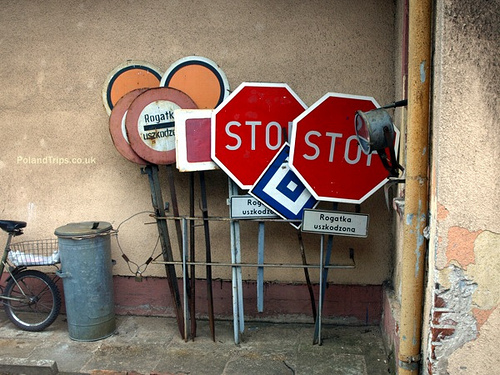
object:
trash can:
[52, 215, 122, 345]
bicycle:
[0, 214, 67, 335]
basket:
[7, 237, 66, 270]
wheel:
[3, 268, 63, 333]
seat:
[0, 217, 31, 240]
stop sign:
[284, 89, 404, 208]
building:
[2, 2, 499, 374]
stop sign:
[207, 80, 312, 315]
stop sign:
[285, 87, 402, 352]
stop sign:
[209, 76, 316, 193]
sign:
[123, 86, 201, 173]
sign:
[108, 87, 173, 168]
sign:
[178, 110, 214, 175]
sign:
[172, 107, 222, 172]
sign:
[159, 54, 233, 120]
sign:
[98, 58, 163, 127]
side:
[0, 1, 396, 327]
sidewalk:
[0, 307, 392, 375]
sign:
[159, 56, 234, 345]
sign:
[100, 57, 191, 348]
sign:
[246, 140, 322, 233]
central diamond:
[285, 179, 298, 193]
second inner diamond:
[274, 168, 310, 201]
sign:
[244, 122, 326, 348]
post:
[140, 164, 186, 340]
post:
[166, 163, 197, 347]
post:
[196, 172, 222, 343]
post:
[295, 230, 324, 350]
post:
[142, 162, 191, 342]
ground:
[3, 310, 390, 374]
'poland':
[15, 153, 48, 166]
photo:
[1, 1, 498, 374]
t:
[244, 117, 263, 152]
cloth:
[3, 248, 60, 271]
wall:
[0, 1, 395, 297]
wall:
[421, 1, 498, 375]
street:
[0, 304, 398, 374]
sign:
[301, 208, 370, 240]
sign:
[228, 195, 285, 219]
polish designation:
[313, 213, 357, 234]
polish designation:
[241, 198, 276, 216]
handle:
[53, 266, 72, 280]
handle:
[111, 256, 118, 267]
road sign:
[248, 140, 326, 351]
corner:
[293, 2, 407, 337]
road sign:
[179, 108, 242, 352]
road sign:
[122, 85, 202, 342]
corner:
[96, 0, 400, 350]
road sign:
[157, 52, 231, 350]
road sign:
[206, 80, 315, 322]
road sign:
[106, 85, 200, 345]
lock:
[133, 269, 145, 284]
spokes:
[8, 275, 57, 326]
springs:
[5, 228, 27, 240]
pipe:
[395, 1, 434, 375]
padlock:
[133, 271, 145, 284]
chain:
[114, 207, 167, 276]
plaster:
[428, 246, 487, 374]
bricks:
[431, 289, 462, 364]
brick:
[430, 295, 461, 311]